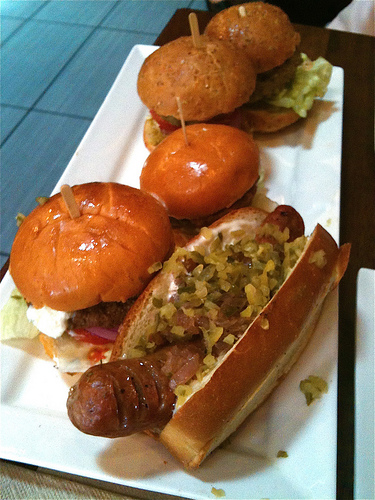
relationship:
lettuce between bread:
[277, 55, 331, 125] [204, 1, 301, 131]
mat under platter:
[2, 460, 142, 499] [1, 44, 345, 499]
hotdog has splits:
[70, 206, 352, 471] [106, 360, 169, 426]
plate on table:
[352, 268, 374, 498] [0, 10, 373, 500]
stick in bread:
[60, 183, 85, 216] [7, 185, 185, 381]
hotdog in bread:
[70, 206, 352, 471] [111, 205, 342, 470]